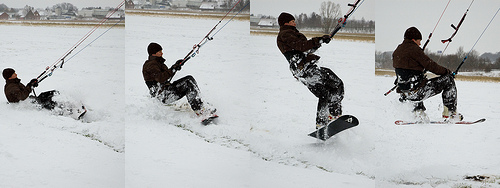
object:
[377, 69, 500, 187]
ground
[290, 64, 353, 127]
ski pants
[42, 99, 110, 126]
tracks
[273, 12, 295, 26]
hat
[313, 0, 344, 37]
tree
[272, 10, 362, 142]
man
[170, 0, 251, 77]
wires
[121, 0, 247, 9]
sky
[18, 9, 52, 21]
homes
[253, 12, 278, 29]
homes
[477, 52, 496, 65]
homes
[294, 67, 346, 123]
black pants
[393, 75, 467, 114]
black pants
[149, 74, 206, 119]
black pants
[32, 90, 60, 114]
black pants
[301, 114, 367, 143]
snowboard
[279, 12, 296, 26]
hat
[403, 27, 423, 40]
hat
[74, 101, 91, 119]
snowboard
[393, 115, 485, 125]
snowboard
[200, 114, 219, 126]
snowboard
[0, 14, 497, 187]
snow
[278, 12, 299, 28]
head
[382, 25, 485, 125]
kite boarder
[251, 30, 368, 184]
ground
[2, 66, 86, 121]
man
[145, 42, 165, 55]
cap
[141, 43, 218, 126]
man